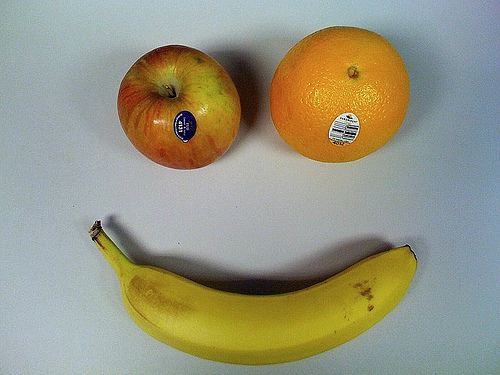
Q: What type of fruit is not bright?
A: The fruit is a banana.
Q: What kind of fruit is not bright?
A: The fruit is a banana.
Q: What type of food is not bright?
A: The food is an apple.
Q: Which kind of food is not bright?
A: The food is an apple.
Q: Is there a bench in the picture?
A: No, there are no benches.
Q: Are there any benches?
A: No, there are no benches.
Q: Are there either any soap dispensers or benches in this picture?
A: No, there are no benches or soap dispensers.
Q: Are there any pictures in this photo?
A: No, there are no pictures.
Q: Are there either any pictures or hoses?
A: No, there are no pictures or hoses.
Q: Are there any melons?
A: No, there are no melons.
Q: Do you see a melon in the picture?
A: No, there are no melons.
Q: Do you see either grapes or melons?
A: No, there are no melons or grapes.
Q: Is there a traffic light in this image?
A: No, there are no traffic lights.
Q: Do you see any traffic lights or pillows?
A: No, there are no traffic lights or pillows.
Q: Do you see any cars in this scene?
A: No, there are no cars.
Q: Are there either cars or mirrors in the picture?
A: No, there are no cars or mirrors.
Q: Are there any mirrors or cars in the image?
A: No, there are no cars or mirrors.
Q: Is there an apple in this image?
A: Yes, there is an apple.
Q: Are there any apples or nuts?
A: Yes, there is an apple.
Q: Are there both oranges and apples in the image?
A: Yes, there are both an apple and oranges.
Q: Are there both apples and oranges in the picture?
A: Yes, there are both an apple and oranges.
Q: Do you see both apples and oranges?
A: Yes, there are both an apple and oranges.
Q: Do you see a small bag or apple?
A: Yes, there is a small apple.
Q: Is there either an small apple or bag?
A: Yes, there is a small apple.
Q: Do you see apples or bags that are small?
A: Yes, the apple is small.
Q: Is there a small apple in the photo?
A: Yes, there is a small apple.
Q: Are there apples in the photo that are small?
A: Yes, there is an apple that is small.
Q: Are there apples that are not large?
A: Yes, there is a small apple.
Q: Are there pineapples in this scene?
A: No, there are no pineapples.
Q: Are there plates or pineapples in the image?
A: No, there are no pineapples or plates.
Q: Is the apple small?
A: Yes, the apple is small.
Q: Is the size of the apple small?
A: Yes, the apple is small.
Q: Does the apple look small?
A: Yes, the apple is small.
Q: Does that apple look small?
A: Yes, the apple is small.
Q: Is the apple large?
A: No, the apple is small.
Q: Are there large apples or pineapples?
A: No, there is an apple but it is small.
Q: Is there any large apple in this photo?
A: No, there is an apple but it is small.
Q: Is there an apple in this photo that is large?
A: No, there is an apple but it is small.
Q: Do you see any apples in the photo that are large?
A: No, there is an apple but it is small.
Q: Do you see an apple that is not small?
A: No, there is an apple but it is small.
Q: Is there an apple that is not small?
A: No, there is an apple but it is small.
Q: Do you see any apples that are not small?
A: No, there is an apple but it is small.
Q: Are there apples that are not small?
A: No, there is an apple but it is small.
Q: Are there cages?
A: No, there are no cages.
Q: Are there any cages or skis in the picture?
A: No, there are no cages or skis.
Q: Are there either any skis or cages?
A: No, there are no cages or skis.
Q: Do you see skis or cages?
A: No, there are no cages or skis.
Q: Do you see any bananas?
A: Yes, there is a banana.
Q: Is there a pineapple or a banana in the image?
A: Yes, there is a banana.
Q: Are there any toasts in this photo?
A: No, there are no toasts.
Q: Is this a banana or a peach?
A: This is a banana.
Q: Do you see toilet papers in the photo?
A: No, there are no toilet papers.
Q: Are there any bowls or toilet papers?
A: No, there are no toilet papers or bowls.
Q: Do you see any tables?
A: Yes, there is a table.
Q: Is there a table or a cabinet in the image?
A: Yes, there is a table.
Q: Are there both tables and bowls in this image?
A: No, there is a table but no bowls.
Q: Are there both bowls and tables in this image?
A: No, there is a table but no bowls.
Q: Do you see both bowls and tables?
A: No, there is a table but no bowls.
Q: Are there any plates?
A: No, there are no plates.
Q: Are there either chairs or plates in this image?
A: No, there are no plates or chairs.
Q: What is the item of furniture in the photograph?
A: The piece of furniture is a table.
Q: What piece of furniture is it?
A: The piece of furniture is a table.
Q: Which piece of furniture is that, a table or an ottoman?
A: This is a table.